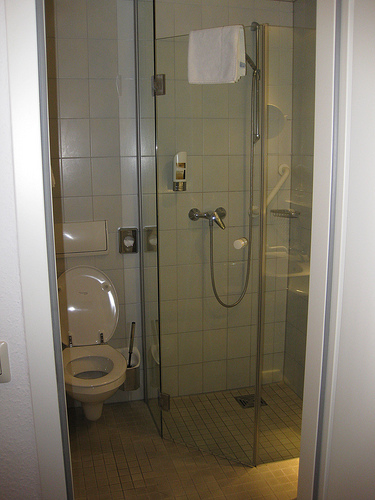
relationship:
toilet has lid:
[50, 262, 142, 427] [55, 262, 123, 346]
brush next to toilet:
[119, 317, 143, 366] [50, 262, 142, 427]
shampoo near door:
[173, 145, 189, 192] [141, 19, 291, 468]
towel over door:
[184, 26, 248, 84] [141, 19, 291, 468]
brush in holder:
[119, 317, 143, 366] [113, 347, 152, 394]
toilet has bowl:
[50, 262, 142, 427] [63, 375, 122, 426]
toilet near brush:
[50, 262, 142, 427] [119, 317, 143, 366]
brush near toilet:
[119, 317, 143, 366] [50, 262, 142, 427]